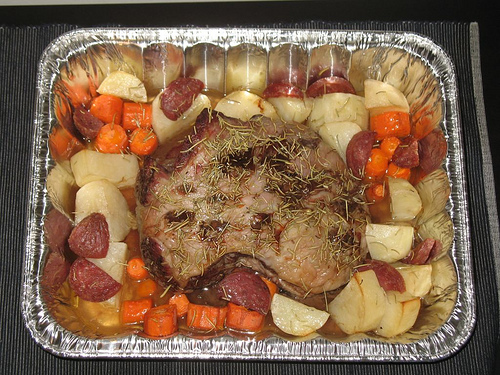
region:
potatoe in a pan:
[275, 288, 326, 336]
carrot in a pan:
[225, 302, 262, 332]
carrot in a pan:
[181, 303, 221, 325]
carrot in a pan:
[150, 300, 175, 341]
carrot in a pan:
[380, 140, 396, 185]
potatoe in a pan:
[350, 271, 383, 331]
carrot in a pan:
[376, 105, 411, 135]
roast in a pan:
[180, 120, 348, 276]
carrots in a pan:
[100, 115, 141, 141]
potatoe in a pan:
[100, 70, 145, 100]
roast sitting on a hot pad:
[6, 15, 496, 372]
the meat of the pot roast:
[131, 103, 373, 302]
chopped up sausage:
[215, 262, 285, 324]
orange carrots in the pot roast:
[123, 251, 225, 335]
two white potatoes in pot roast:
[67, 148, 139, 232]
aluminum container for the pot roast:
[20, 22, 479, 364]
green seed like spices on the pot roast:
[194, 133, 311, 193]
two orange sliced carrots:
[90, 119, 157, 160]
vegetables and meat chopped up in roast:
[65, 68, 145, 329]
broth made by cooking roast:
[82, 301, 118, 328]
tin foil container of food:
[22, 25, 477, 362]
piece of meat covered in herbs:
[143, 110, 356, 292]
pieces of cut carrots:
[97, 98, 154, 150]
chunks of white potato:
[271, 261, 433, 336]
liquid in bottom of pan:
[77, 278, 144, 330]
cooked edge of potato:
[399, 296, 419, 313]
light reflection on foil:
[114, 25, 354, 46]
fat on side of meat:
[169, 123, 349, 289]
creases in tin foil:
[74, 343, 441, 356]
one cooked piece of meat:
[131, 108, 370, 295]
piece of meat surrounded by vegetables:
[76, 75, 429, 335]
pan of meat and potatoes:
[25, 20, 477, 365]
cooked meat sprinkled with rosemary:
[141, 115, 364, 294]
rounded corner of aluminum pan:
[28, 17, 123, 79]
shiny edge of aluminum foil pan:
[32, 334, 469, 374]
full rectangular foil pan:
[18, 15, 479, 364]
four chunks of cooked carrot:
[86, 95, 161, 155]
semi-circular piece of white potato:
[266, 286, 331, 336]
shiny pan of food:
[15, 20, 477, 374]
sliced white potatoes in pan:
[76, 150, 130, 201]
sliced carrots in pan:
[123, 307, 248, 340]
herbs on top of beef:
[218, 144, 304, 230]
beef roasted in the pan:
[148, 140, 350, 286]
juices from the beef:
[81, 301, 171, 337]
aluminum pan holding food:
[40, 40, 469, 360]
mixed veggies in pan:
[72, 84, 137, 270]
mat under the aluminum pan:
[3, 31, 483, 374]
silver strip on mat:
[470, 29, 490, 136]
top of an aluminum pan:
[58, 42, 255, 69]